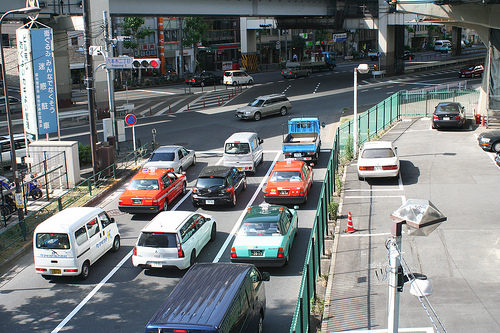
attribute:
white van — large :
[32, 205, 120, 280]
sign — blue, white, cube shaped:
[16, 28, 56, 135]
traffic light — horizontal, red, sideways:
[130, 56, 163, 69]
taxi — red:
[111, 162, 186, 218]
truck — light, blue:
[281, 116, 323, 163]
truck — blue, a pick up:
[283, 115, 321, 159]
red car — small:
[262, 158, 317, 207]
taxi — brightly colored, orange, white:
[130, 151, 192, 211]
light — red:
[130, 51, 168, 81]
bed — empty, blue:
[288, 132, 318, 148]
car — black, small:
[343, 107, 411, 213]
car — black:
[426, 96, 473, 141]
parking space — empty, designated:
[341, 192, 413, 243]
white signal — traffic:
[107, 50, 160, 69]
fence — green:
[283, 77, 470, 328]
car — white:
[355, 139, 402, 180]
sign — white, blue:
[11, 10, 63, 135]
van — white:
[36, 199, 123, 284]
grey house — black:
[134, 255, 276, 331]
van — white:
[29, 205, 123, 279]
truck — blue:
[279, 113, 326, 162]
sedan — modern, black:
[183, 162, 251, 213]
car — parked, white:
[357, 142, 399, 180]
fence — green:
[288, 94, 406, 328]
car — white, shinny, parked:
[353, 139, 401, 186]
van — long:
[155, 251, 270, 328]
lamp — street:
[21, 10, 60, 33]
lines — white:
[340, 224, 394, 243]